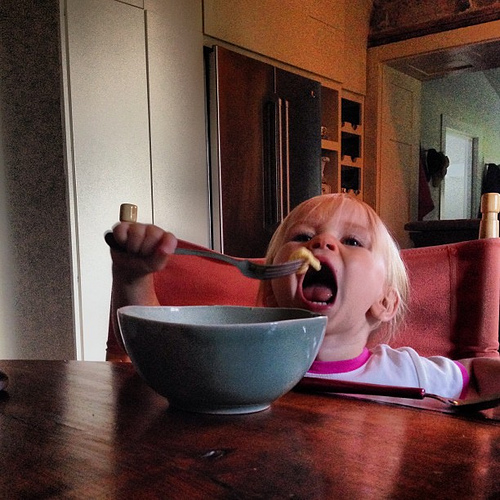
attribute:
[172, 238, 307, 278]
fork — silver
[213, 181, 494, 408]
child — blonde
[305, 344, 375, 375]
collar — pink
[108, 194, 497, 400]
girl — little, eating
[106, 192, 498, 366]
chair — wooden, fabric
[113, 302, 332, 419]
ceramic bowl — large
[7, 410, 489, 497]
table surface — brown, wooden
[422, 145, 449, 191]
brown hat — hanging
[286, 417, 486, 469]
table — shiny, dark, brown, wooden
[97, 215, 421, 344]
fork — metal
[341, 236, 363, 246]
eye — dark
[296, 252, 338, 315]
mouth — open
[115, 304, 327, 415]
bowl — blue, ceramic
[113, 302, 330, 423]
bowl — big, white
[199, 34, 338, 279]
refrigerator — metal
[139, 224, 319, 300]
fork — silver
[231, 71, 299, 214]
refrigerator — stainless steel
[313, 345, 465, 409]
shirt — pink, white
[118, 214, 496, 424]
chair — red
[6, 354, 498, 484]
table — wooden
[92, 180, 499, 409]
boy — little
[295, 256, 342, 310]
mouth — open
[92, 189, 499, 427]
kid — young